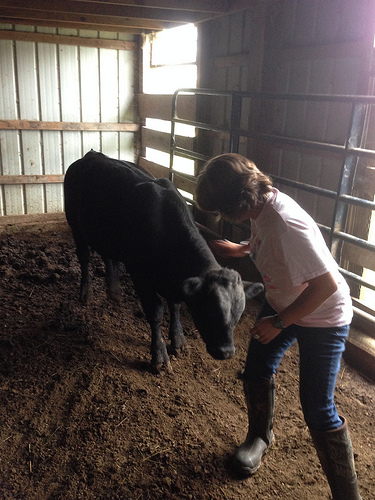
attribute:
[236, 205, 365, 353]
shirt — white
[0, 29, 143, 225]
slats — wooden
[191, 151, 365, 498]
lady — brown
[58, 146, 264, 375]
cow — black, young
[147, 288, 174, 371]
leg — front right leg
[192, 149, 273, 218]
hair — short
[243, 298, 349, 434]
jeans — blue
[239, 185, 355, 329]
shirt — white, sleeveless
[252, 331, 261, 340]
ring — wedding ring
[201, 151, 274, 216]
hair — short , brown 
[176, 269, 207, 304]
ear — black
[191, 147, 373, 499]
woman — blonde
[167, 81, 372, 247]
guard — metal cattle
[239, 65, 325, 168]
bars — metal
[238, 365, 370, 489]
boots — black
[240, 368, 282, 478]
boots — brown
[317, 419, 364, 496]
boots — brown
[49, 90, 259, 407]
cow — black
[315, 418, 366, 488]
boot — brown, tall, rubber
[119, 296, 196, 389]
legs — front legs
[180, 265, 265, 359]
head — cow's head